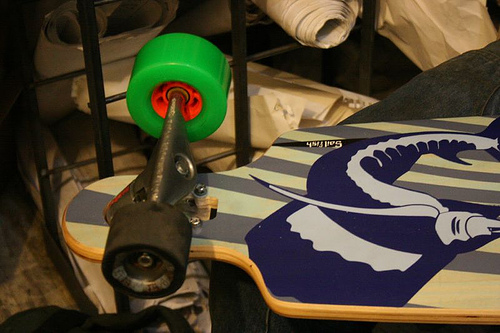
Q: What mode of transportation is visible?
A: Skateboard.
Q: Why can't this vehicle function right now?
A: One of it's wheels is missing.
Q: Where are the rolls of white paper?
A: On the other side of the skateboard.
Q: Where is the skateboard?
A: On a person's lap.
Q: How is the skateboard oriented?
A: Upside down.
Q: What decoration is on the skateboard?
A: A blue and white picture of a fish.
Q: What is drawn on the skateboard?
A: A dolphin.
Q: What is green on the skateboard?
A: Wheels.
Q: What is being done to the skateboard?
A: Repair.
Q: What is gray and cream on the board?
A: Stripes.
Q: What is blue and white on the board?
A: The dolphin.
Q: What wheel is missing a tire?
A: Right wheel.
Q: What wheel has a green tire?
A: The left wheel.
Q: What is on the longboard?
A: Blue and white graphic.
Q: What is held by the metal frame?
A: A roll of paper.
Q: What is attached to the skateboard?
A: A green wheel.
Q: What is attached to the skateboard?
A: A green and orange wheel.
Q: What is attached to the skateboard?
A: A green and orange wheel.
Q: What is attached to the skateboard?
A: A black wheel.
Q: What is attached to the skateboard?
A: Different colored wheels.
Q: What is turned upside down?
A: A skateboard.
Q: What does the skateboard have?
A: Two different wheels.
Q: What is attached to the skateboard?
A: A green wheel.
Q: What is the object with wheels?
A: A skateboard.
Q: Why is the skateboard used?
A: For fun.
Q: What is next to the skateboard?
A: Rolled paper.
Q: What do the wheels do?
A: Spin.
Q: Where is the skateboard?
A: On a lap.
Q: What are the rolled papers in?
A: A wire rack.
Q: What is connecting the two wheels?
A: A metal rod.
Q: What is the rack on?
A: The floor.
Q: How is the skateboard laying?
A: Upside down.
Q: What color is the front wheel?
A: Black.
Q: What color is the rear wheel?
A: Green.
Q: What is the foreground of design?
A: Elephant.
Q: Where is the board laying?
A: Table.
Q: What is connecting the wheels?
A: Axle.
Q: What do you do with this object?
A: Ride it.